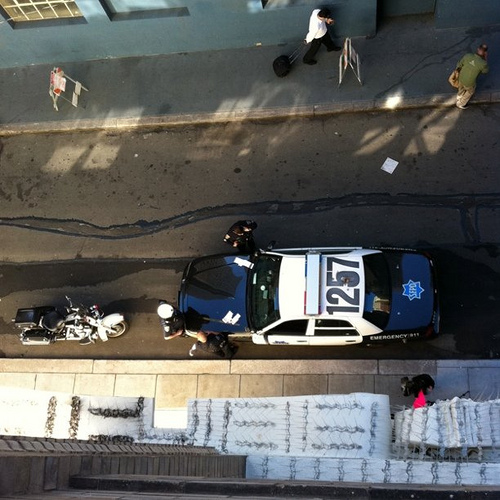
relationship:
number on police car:
[326, 255, 359, 316] [175, 238, 442, 346]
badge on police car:
[401, 278, 425, 301] [175, 238, 442, 346]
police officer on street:
[157, 297, 189, 340] [0, 102, 499, 361]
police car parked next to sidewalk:
[175, 238, 442, 346] [0, 356, 499, 406]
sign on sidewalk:
[49, 66, 88, 112] [0, 25, 500, 135]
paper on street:
[380, 157, 398, 176] [0, 102, 499, 361]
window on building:
[0, 1, 88, 28] [0, 0, 499, 70]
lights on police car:
[303, 250, 322, 317] [175, 238, 442, 346]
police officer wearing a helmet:
[157, 297, 189, 340] [157, 303, 175, 320]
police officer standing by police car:
[157, 297, 189, 340] [175, 238, 442, 346]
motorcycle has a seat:
[12, 293, 128, 346] [42, 311, 67, 331]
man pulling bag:
[304, 7, 343, 64] [273, 54, 292, 76]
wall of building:
[0, 0, 498, 69] [0, 0, 499, 70]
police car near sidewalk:
[175, 238, 442, 346] [0, 356, 499, 406]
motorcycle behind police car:
[12, 293, 128, 346] [175, 238, 442, 346]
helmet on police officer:
[157, 303, 175, 320] [157, 297, 189, 340]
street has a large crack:
[0, 102, 499, 361] [0, 187, 498, 245]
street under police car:
[0, 102, 499, 361] [175, 238, 442, 346]